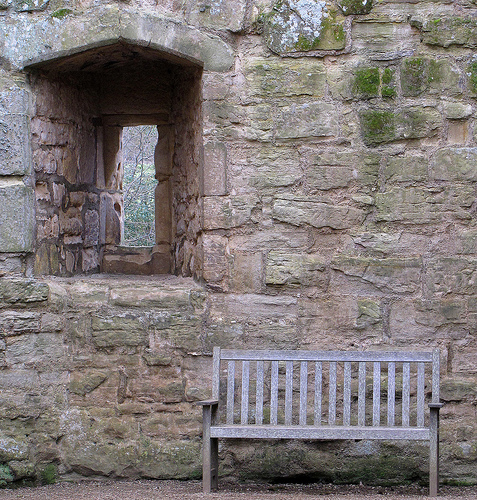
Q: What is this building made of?
A: Brick.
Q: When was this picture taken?
A: Daytime.